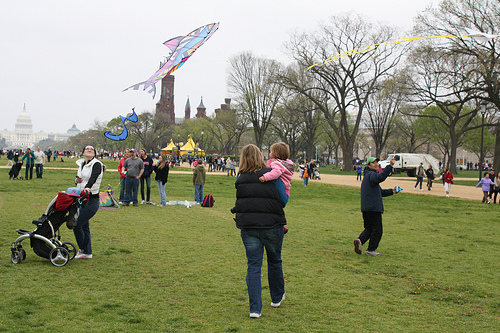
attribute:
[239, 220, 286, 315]
jeans — Blue 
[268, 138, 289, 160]
hair — brown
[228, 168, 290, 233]
vest — black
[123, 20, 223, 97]
kite — shape of a shark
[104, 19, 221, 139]
kite — blue and pink, flying in the air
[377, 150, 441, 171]
truck — garbage, white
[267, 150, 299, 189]
jacket — pink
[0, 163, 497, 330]
grass — green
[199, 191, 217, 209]
backpack — red, black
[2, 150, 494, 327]
park — public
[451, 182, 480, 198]
walkway — in the picture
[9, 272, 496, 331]
grass — green